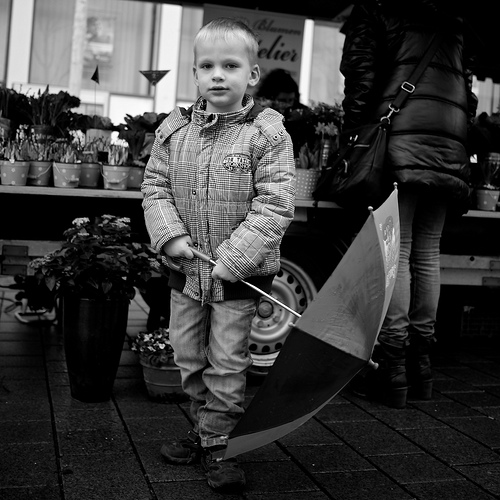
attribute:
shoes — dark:
[163, 427, 251, 492]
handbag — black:
[317, 114, 395, 204]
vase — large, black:
[53, 282, 134, 403]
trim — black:
[166, 267, 275, 303]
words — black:
[252, 17, 303, 68]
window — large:
[23, 1, 163, 104]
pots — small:
[4, 157, 146, 191]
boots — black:
[378, 345, 436, 405]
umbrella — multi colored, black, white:
[176, 173, 408, 465]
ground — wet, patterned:
[2, 308, 499, 499]